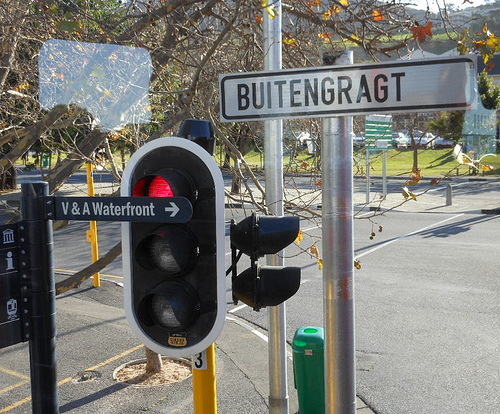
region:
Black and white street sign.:
[211, 55, 473, 133]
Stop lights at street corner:
[115, 110, 305, 350]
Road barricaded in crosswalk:
[440, 175, 452, 211]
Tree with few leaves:
[0, 35, 270, 225]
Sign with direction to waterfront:
[5, 170, 200, 235]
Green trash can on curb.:
[280, 315, 330, 410]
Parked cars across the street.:
[390, 121, 470, 141]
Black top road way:
[16, 141, 491, 398]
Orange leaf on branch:
[405, 16, 436, 48]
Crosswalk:
[273, 203, 476, 268]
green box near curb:
[290, 323, 328, 412]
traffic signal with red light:
[116, 132, 225, 353]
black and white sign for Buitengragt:
[217, 59, 479, 120]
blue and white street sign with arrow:
[49, 192, 194, 222]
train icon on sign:
[5, 295, 20, 322]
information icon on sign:
[1, 249, 18, 271]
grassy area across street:
[21, 145, 498, 173]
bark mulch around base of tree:
[116, 356, 193, 384]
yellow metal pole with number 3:
[189, 343, 217, 412]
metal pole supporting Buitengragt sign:
[321, 57, 359, 412]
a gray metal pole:
[304, 44, 367, 411]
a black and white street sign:
[208, 50, 498, 129]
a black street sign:
[40, 185, 199, 230]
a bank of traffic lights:
[113, 134, 230, 367]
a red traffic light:
[130, 170, 176, 197]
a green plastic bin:
[285, 315, 324, 412]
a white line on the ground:
[354, 210, 464, 265]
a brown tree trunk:
[142, 347, 164, 373]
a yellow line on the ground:
[0, 340, 145, 412]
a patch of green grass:
[15, 137, 498, 173]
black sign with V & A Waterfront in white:
[48, 196, 192, 222]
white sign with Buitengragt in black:
[214, 57, 476, 120]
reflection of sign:
[33, 36, 152, 129]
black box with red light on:
[119, 131, 225, 353]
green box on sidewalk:
[292, 324, 325, 409]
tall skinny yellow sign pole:
[83, 154, 100, 284]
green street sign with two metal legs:
[365, 111, 395, 204]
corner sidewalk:
[6, 266, 367, 411]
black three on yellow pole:
[191, 350, 208, 369]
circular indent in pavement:
[113, 356, 191, 386]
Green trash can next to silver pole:
[290, 315, 324, 412]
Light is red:
[131, 170, 188, 220]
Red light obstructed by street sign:
[133, 178, 193, 217]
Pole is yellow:
[189, 345, 218, 410]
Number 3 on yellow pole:
[192, 352, 206, 368]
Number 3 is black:
[190, 348, 203, 369]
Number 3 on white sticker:
[195, 351, 202, 366]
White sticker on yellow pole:
[189, 350, 207, 370]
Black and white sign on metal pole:
[216, 48, 472, 116]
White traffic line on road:
[230, 208, 470, 322]